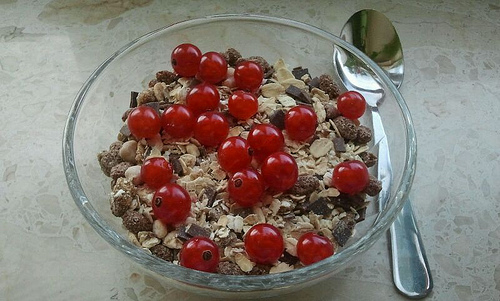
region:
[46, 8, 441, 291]
A bow filled with food.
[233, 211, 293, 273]
a cherry in a bowl.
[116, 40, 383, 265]
a group of cherries.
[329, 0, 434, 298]
a metal spoon on a table.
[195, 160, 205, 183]
a mixture of cereal.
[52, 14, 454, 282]
a bowl of cereal.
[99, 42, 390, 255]
cereal in a bowl.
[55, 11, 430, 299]
a bowl of cherries.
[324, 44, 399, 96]
light reflecting on a spoon.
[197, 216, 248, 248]
A section of cereal in a bowl.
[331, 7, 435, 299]
Silver spoon to the right of a clear bowl.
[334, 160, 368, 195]
Red cherry close to a silver spoon base.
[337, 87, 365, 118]
Small red cherry over the top of a spoon.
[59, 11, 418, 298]
A clear bowl full of granola and cherries.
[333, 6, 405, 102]
Silver round end of a spoon.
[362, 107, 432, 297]
Long silver handle of a spoon.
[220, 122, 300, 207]
Four cherries in the middle of a bowl close together.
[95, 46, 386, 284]
Granola, nuts and cherries all in the clear bowl.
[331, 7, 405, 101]
Oval end of a silver spoon.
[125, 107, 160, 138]
Red round cherry to the left side of the clear bowl.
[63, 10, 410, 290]
A glass bowl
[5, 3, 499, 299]
A granite surface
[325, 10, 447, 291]
A silver spoon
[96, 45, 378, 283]
some cereal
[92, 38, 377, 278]
oats in the bowl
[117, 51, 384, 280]
nuts in the bowl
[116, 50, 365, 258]
chocolate shavings in the bowl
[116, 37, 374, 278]
cherries in the bowl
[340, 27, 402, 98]
reflections in the spoon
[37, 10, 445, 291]
A healthy cereal with cherries in a glass bowl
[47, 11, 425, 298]
a person is about to eat this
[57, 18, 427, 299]
a bowl of cereal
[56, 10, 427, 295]
a clear bowl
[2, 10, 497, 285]
a gray table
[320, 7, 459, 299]
a silver spoon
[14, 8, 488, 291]
a scene inside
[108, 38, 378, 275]
some red cherries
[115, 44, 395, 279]
some chocolate chips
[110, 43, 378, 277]
some oatmeal flakes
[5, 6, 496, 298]
a photo that was taken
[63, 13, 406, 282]
CLEAR GLASS BOWL WITH CEREAL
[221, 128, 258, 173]
RED BERRIES ATOP CEREAL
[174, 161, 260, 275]
OAT AND GRAIN CEREAL IN BOWL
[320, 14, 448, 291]
SILVER SPOON NEXT TO BOWL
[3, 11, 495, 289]
WHITE COUNTER TOP UNDER BOWL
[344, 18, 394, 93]
REFLECTION IN SILVER SPOON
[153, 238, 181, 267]
BROWN RAISENS IN BOWL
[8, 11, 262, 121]
SHADOW OF OBJECT STONE COUNTER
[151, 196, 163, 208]
DARK STEM BASE ON RED BERRY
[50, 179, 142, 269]
EDGE OF CLEAR GLASS